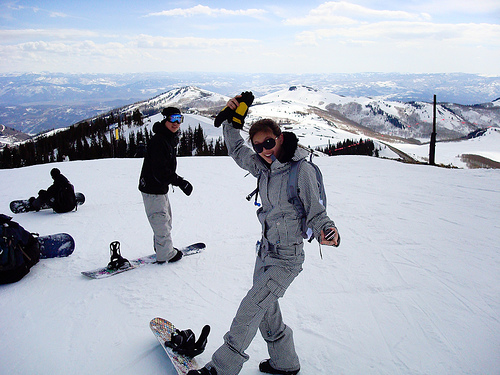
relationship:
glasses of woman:
[253, 135, 281, 153] [172, 92, 330, 373]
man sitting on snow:
[29, 167, 81, 214] [2, 159, 498, 373]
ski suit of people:
[206, 124, 339, 375] [176, 89, 339, 375]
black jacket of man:
[138, 119, 181, 196] [135, 104, 202, 266]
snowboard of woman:
[128, 311, 245, 374] [209, 94, 346, 374]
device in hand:
[318, 227, 335, 242] [316, 222, 338, 249]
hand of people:
[316, 222, 338, 249] [176, 89, 339, 375]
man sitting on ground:
[29, 167, 81, 214] [1, 156, 497, 372]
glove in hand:
[210, 87, 256, 134] [224, 89, 245, 111]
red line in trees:
[332, 143, 361, 153] [312, 132, 379, 155]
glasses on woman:
[247, 135, 282, 161] [201, 112, 353, 373]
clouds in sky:
[1, 0, 499, 75] [0, 0, 499, 135]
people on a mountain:
[142, 84, 351, 373] [4, 139, 498, 373]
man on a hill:
[137, 106, 192, 263] [4, 152, 494, 373]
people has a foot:
[176, 89, 339, 375] [192, 362, 243, 374]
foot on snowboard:
[192, 362, 243, 374] [152, 314, 205, 371]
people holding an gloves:
[176, 89, 339, 375] [226, 95, 254, 128]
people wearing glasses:
[176, 89, 339, 375] [253, 135, 281, 153]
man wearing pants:
[137, 106, 192, 263] [140, 190, 177, 262]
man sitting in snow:
[29, 167, 81, 214] [374, 190, 499, 329]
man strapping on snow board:
[137, 106, 192, 263] [76, 235, 226, 286]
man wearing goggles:
[137, 106, 192, 263] [166, 114, 184, 121]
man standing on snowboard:
[137, 106, 192, 263] [81, 242, 204, 280]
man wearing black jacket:
[137, 106, 192, 263] [134, 114, 182, 196]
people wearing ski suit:
[176, 89, 339, 375] [220, 143, 323, 372]